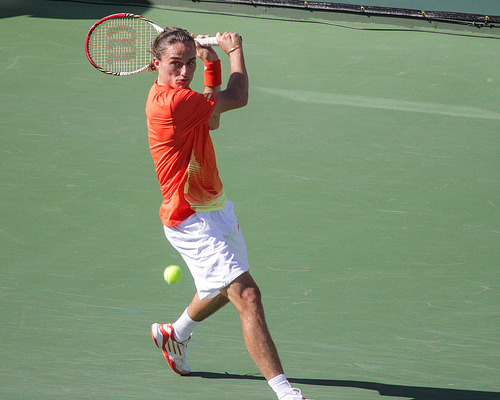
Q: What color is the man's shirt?
A: Orange.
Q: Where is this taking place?
A: Tennis court.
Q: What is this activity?
A: Tennis.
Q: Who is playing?
A: A man.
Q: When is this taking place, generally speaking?
A: During the day.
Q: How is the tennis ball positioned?
A: In the air.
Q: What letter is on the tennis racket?
A: W.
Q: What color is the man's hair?
A: Brown.